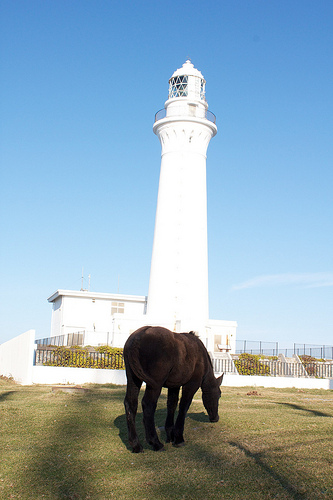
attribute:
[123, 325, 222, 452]
horse — black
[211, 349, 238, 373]
stairs — white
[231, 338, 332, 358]
fence — black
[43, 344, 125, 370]
bushes — yellow green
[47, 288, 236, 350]
house — white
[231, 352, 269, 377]
leaves — green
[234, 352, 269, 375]
bush — green